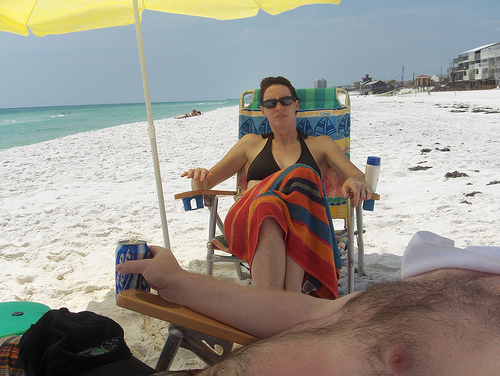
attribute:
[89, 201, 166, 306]
can — beer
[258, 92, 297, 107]
sunglasses — black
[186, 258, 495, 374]
chest — shirtless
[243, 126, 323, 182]
top — black, bathing suit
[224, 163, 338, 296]
towel — colorful, beach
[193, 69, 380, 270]
woman — sitting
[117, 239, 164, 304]
beer — budlight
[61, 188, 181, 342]
can — beer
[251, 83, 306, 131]
glasses — sun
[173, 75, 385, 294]
chair — lounge